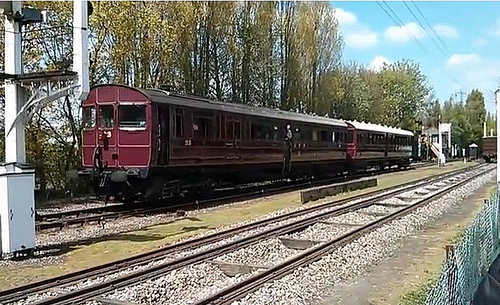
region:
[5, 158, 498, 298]
train tracks with stones along the rails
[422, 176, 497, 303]
a green mesh fence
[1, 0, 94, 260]
railroad crossing lights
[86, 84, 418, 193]
a burgundy and black passenger train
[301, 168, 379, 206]
a rail not used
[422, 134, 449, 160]
a stairway down the track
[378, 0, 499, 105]
overhead utility lines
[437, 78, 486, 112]
a ferris wheel appears over the trees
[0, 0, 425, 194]
trees stand along the train bed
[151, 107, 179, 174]
the entry door into the car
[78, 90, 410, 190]
burgundy train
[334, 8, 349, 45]
white clouds in blue sky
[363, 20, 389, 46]
white clouds in blue sky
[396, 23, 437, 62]
white clouds in blue sky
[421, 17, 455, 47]
white clouds in blue sky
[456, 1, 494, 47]
white clouds in blue sky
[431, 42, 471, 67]
white clouds in blue sky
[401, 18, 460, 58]
white clouds in blue sky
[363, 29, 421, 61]
white clouds in blue sky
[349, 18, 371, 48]
white clouds in blue sky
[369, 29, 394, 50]
white clouds in blue sky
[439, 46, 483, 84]
white clouds in blue sky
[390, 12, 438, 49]
white clouds in blue sky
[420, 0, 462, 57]
white clouds in blue sky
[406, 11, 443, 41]
white clouds in blue sky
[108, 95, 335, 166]
burgundy train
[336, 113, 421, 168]
burgundy train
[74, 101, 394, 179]
brown train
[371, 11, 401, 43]
white clouds in blue sky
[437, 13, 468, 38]
white clouds in blue sky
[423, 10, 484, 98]
white clouds in blue sky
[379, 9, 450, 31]
white clouds in blue sky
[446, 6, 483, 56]
white clouds in blue sky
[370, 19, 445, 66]
white clouds in blue sky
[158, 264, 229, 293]
Part of train track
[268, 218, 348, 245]
Part of train track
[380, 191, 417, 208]
Part of train track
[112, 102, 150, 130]
Window on red train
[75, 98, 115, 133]
Window on red train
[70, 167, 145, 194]
Coupling on red train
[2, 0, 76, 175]
Signal light near red train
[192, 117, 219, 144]
Window on red train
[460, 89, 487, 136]
Green tree near train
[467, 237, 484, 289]
Chain link fence near train